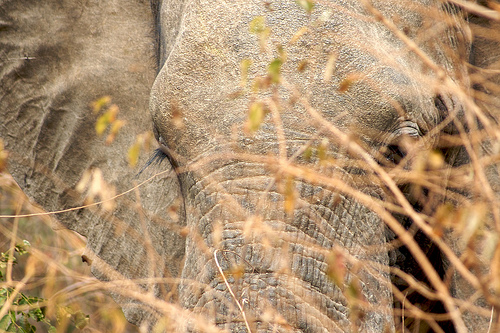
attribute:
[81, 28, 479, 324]
elephant — close view, gray, dark, brown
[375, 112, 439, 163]
eye — dark, socket, gray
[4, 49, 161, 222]
ear — sharp, dark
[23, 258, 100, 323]
leave — dried, blurry, green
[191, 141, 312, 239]
skin — curved, broken, gray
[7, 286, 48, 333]
plant — green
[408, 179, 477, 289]
grass — brown, dead